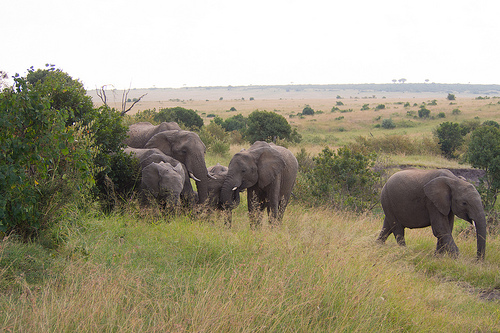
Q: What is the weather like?
A: It is clear.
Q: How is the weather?
A: It is clear.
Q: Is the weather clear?
A: Yes, it is clear.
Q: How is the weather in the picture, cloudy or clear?
A: It is clear.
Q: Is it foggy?
A: No, it is clear.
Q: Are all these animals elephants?
A: Yes, all the animals are elephants.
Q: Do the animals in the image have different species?
A: No, all the animals are elephants.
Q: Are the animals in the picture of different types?
A: No, all the animals are elephants.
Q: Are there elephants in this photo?
A: Yes, there are elephants.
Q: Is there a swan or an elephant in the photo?
A: Yes, there are elephants.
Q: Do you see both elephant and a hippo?
A: No, there are elephants but no hippos.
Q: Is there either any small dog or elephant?
A: Yes, there are small elephants.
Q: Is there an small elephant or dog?
A: Yes, there are small elephants.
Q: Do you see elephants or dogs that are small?
A: Yes, the elephants are small.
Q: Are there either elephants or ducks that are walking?
A: Yes, the elephants are walking.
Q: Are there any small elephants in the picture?
A: Yes, there are small elephants.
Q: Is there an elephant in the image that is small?
A: Yes, there are elephants that are small.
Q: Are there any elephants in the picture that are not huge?
A: Yes, there are small elephants.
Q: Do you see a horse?
A: No, there are no horses.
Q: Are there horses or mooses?
A: No, there are no horses or mooses.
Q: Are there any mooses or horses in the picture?
A: No, there are no horses or mooses.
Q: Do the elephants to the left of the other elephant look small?
A: Yes, the elephants are small.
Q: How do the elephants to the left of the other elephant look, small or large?
A: The elephants are small.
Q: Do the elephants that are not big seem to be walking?
A: Yes, the elephants are walking.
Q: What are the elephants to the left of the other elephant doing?
A: The elephants are walking.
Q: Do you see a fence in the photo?
A: No, there are no fences.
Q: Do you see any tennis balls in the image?
A: No, there are no tennis balls.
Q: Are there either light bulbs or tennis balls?
A: No, there are no tennis balls or light bulbs.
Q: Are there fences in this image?
A: No, there are no fences.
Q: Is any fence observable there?
A: No, there are no fences.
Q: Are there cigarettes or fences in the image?
A: No, there are no fences or cigarettes.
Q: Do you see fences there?
A: No, there are no fences.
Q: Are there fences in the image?
A: No, there are no fences.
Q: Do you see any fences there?
A: No, there are no fences.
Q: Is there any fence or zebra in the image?
A: No, there are no fences or zebras.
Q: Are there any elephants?
A: Yes, there is an elephant.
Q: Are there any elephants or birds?
A: Yes, there is an elephant.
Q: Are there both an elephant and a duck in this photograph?
A: No, there is an elephant but no ducks.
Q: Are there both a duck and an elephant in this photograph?
A: No, there is an elephant but no ducks.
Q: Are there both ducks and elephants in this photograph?
A: No, there is an elephant but no ducks.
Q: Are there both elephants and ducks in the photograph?
A: No, there is an elephant but no ducks.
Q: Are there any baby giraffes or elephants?
A: Yes, there is a baby elephant.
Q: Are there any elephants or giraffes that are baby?
A: Yes, the elephant is a baby.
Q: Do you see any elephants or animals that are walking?
A: Yes, the elephant is walking.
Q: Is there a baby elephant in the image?
A: Yes, there is a baby elephant.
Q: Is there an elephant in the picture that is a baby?
A: Yes, there is an elephant that is a baby.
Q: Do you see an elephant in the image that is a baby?
A: Yes, there is an elephant that is a baby.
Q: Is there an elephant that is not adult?
A: Yes, there is an baby elephant.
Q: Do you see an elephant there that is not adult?
A: Yes, there is an baby elephant.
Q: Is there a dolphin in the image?
A: No, there are no dolphins.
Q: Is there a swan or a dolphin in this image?
A: No, there are no dolphins or swans.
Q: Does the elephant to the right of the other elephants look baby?
A: Yes, the elephant is a baby.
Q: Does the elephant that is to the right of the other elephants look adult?
A: No, the elephant is a baby.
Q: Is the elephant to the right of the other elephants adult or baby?
A: The elephant is a baby.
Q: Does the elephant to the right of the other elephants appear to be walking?
A: Yes, the elephant is walking.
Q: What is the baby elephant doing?
A: The elephant is walking.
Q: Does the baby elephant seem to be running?
A: No, the elephant is walking.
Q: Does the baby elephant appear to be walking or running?
A: The elephant is walking.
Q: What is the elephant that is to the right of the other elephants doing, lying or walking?
A: The elephant is walking.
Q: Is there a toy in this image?
A: No, there are no toys.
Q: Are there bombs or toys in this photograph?
A: No, there are no toys or bombs.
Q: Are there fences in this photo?
A: No, there are no fences.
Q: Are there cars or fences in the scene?
A: No, there are no fences or cars.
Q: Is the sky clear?
A: Yes, the sky is clear.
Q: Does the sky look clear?
A: Yes, the sky is clear.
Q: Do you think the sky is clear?
A: Yes, the sky is clear.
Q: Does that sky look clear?
A: Yes, the sky is clear.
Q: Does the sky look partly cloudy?
A: No, the sky is clear.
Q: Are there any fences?
A: No, there are no fences.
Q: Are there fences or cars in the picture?
A: No, there are no fences or cars.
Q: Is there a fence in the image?
A: No, there are no fences.